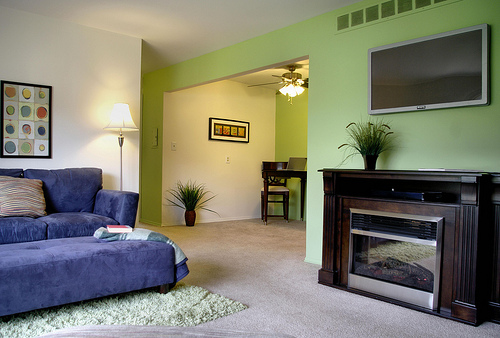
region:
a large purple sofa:
[0, 165, 141, 243]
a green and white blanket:
[92, 225, 190, 282]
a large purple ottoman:
[2, 235, 175, 317]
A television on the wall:
[363, 19, 488, 117]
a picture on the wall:
[210, 114, 251, 144]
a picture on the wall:
[0, 78, 54, 159]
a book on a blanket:
[104, 220, 134, 232]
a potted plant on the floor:
[161, 181, 220, 225]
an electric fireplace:
[309, 162, 499, 324]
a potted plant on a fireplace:
[333, 114, 397, 172]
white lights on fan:
[269, 72, 317, 114]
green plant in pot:
[160, 179, 212, 234]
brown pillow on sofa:
[2, 174, 42, 222]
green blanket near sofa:
[88, 219, 183, 266]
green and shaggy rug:
[3, 299, 263, 336]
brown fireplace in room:
[317, 165, 494, 333]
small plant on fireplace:
[348, 109, 380, 169]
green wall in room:
[392, 127, 499, 163]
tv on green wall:
[360, 39, 493, 115]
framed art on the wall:
[208, 115, 251, 142]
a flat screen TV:
[362, 24, 492, 114]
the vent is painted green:
[335, 0, 450, 32]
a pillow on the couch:
[0, 177, 47, 214]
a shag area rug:
[0, 287, 247, 329]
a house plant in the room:
[163, 180, 213, 220]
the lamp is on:
[105, 103, 137, 190]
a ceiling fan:
[252, 66, 307, 100]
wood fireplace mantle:
[316, 168, 484, 203]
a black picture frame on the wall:
[174, 90, 258, 148]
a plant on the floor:
[145, 166, 235, 244]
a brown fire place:
[293, 145, 493, 322]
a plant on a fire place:
[285, 110, 496, 305]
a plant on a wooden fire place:
[313, 122, 484, 272]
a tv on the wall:
[334, 38, 494, 124]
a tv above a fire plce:
[323, 41, 494, 287]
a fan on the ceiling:
[232, 55, 354, 126]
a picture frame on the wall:
[0, 73, 80, 179]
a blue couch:
[4, 168, 186, 272]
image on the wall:
[201, 110, 261, 155]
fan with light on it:
[241, 73, 316, 103]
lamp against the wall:
[99, 95, 140, 191]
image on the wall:
[2, 66, 62, 158]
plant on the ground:
[161, 174, 210, 231]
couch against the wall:
[6, 155, 145, 228]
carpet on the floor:
[213, 222, 298, 316]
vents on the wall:
[328, 5, 411, 28]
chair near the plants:
[255, 154, 293, 224]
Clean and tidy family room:
[1, 1, 498, 336]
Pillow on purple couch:
[2, 165, 140, 245]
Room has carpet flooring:
[0, 1, 498, 336]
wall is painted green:
[140, 0, 499, 315]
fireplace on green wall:
[311, 162, 498, 324]